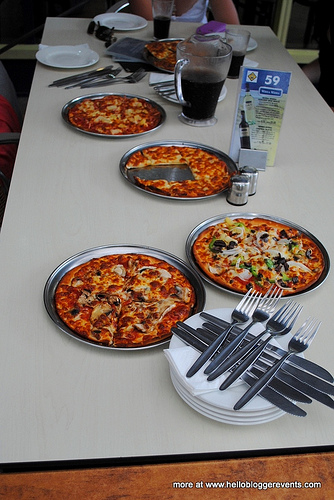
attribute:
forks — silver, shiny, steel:
[184, 288, 321, 416]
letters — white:
[170, 481, 323, 491]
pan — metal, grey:
[43, 243, 205, 351]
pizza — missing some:
[124, 144, 230, 197]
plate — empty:
[34, 44, 95, 69]